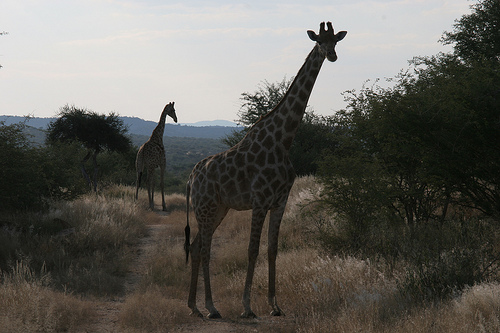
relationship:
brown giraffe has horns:
[182, 21, 347, 319] [318, 21, 335, 33]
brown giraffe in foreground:
[182, 21, 347, 319] [322, 208, 499, 319]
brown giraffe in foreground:
[182, 21, 347, 319] [313, 233, 462, 322]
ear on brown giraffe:
[307, 29, 320, 41] [182, 21, 347, 319]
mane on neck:
[254, 47, 312, 126] [261, 49, 318, 148]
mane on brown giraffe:
[254, 47, 312, 126] [182, 21, 347, 319]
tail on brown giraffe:
[169, 174, 202, 264] [182, 21, 347, 319]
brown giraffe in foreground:
[182, 21, 347, 319] [354, 245, 496, 330]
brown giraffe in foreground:
[182, 21, 347, 319] [332, 190, 499, 270]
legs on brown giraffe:
[237, 204, 312, 328] [182, 21, 347, 319]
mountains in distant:
[20, 84, 201, 166] [33, 42, 152, 128]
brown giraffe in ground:
[135, 101, 178, 212] [72, 225, 314, 331]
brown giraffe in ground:
[182, 21, 347, 319] [72, 225, 314, 331]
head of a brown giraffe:
[307, 20, 347, 62] [182, 21, 347, 319]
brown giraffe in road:
[182, 21, 347, 319] [144, 211, 217, 331]